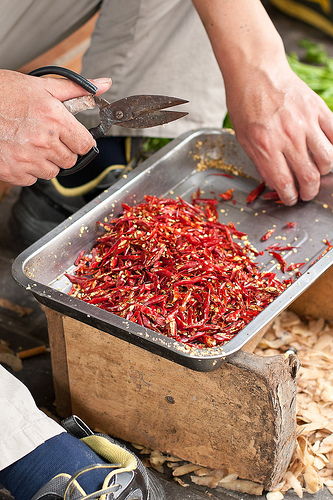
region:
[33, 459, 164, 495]
untied shoe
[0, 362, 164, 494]
pant leg and foot in shoe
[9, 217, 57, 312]
edge of a tin tray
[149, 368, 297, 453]
block of wood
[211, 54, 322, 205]
hand reaching into the tray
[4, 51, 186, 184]
man holding a pair of shears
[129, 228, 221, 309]
cut red chile peppers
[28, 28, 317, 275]
man working over a tray of peppers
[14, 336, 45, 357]
cigarette butt on the ground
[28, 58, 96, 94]
plastic covered handle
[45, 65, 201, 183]
a form of scissors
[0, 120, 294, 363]
silver pan of red peppers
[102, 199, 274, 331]
a pile of small red peppers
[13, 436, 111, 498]
a blue sock in a shoe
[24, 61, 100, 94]
a black handle on scissors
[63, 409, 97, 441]
black tab to help pull shoes on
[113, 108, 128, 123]
screw in middle of scissors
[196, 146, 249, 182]
seeds in corner of pan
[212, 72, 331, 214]
a hand picking up pepper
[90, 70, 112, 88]
a finger nail on the thumb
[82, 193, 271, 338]
tiny red chilis and chili seeds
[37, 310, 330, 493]
block of natural wood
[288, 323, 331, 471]
pile of wood shavings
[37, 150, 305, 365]
silver tray full of tiny chili peppers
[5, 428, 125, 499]
navy blue sock inside of shoe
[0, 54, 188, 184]
right hand grasping pruning shears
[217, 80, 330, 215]
left hand scooping up chili peppers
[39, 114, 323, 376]
silver tray is messy with chilis and seeds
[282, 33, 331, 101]
greenery out of focus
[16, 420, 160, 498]
silver and black tennis shoes with butter yellow interior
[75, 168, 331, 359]
A tin full of peppers.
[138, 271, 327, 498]
Wood shavings.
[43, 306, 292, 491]
A block of wood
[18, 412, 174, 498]
Part of a tennis shoe.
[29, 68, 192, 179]
A rusty pair of sissors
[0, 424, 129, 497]
Someones blue sock.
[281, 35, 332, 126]
Part of a green veggie.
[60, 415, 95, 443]
Pull tag on the back of the shoe.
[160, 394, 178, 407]
A screw or nail in the wood block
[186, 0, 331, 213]
A hand holding the peppers.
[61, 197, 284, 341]
these are red chilies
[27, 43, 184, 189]
a pair of old rusted scissors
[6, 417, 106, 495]
the man is wearing blue socks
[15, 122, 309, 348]
the red chilies are on a silver tray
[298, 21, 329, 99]
some green blurred out leaves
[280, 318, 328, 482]
some dried out leaves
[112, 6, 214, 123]
the man is wearing light tan pants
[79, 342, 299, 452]
a wooden stool turned over on its side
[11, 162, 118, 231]
the mans tennis shoe is black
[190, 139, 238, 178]
the seeds from the inside of the chilies